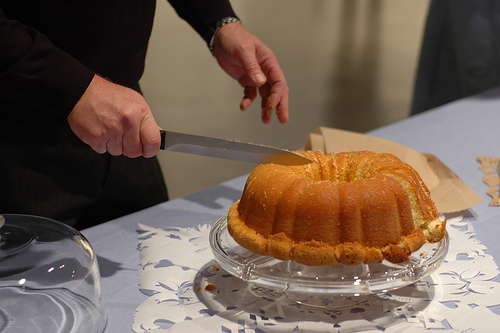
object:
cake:
[227, 150, 446, 266]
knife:
[159, 128, 313, 166]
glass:
[208, 214, 450, 308]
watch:
[204, 16, 241, 55]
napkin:
[299, 126, 483, 213]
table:
[0, 87, 500, 332]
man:
[1, 4, 290, 242]